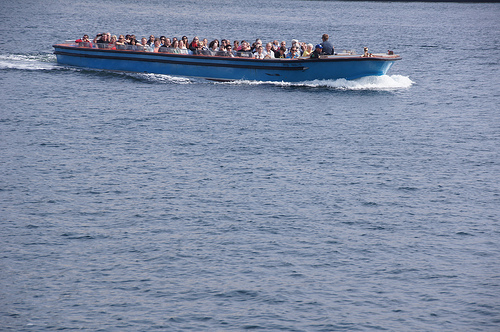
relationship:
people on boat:
[130, 39, 276, 49] [58, 50, 401, 86]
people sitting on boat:
[130, 39, 276, 49] [58, 50, 401, 86]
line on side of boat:
[56, 59, 310, 76] [58, 50, 401, 86]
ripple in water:
[98, 167, 227, 230] [32, 76, 499, 237]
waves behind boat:
[6, 47, 53, 75] [58, 50, 401, 86]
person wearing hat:
[311, 25, 327, 58] [313, 51, 322, 52]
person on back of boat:
[81, 33, 96, 50] [48, 33, 122, 72]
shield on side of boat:
[118, 45, 223, 59] [58, 50, 401, 86]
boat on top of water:
[58, 50, 401, 86] [346, 75, 426, 94]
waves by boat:
[6, 47, 53, 75] [58, 50, 401, 86]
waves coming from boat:
[6, 47, 53, 75] [58, 50, 401, 86]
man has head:
[317, 30, 339, 60] [320, 32, 327, 40]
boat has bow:
[58, 50, 401, 86] [367, 50, 405, 69]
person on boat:
[311, 25, 327, 58] [58, 50, 401, 86]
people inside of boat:
[130, 39, 276, 49] [58, 50, 401, 86]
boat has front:
[58, 50, 401, 86] [338, 51, 419, 87]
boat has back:
[58, 50, 401, 86] [40, 44, 114, 68]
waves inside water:
[6, 47, 53, 75] [32, 76, 499, 237]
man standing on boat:
[317, 30, 339, 60] [58, 50, 401, 86]